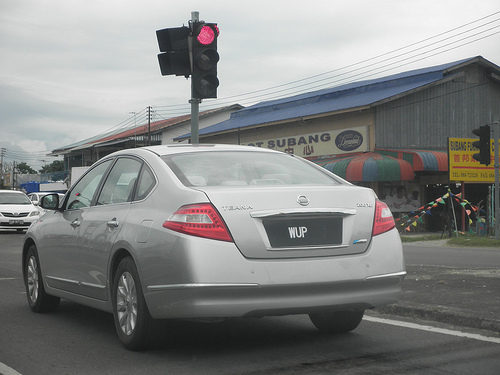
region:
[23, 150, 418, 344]
the car is silver in color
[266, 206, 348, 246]
the car has no numberplates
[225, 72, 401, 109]
the roof is blue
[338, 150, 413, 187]
the awing i red and blue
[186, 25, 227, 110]
the traaffic light is red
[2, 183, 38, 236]
the car is white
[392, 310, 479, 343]
the line is white in color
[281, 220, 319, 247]
wup letters are on the plate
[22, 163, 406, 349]
the car is brand new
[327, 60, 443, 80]
electric wires are in the air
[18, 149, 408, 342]
a silver car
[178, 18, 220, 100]
a street sign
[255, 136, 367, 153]
writing on the side of the building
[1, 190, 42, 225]
a white car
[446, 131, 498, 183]
a yellow sign on the building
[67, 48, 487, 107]
wires from the telephone poles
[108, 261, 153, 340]
the tire of the car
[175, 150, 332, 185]
the back window of the car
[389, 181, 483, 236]
flags in front of the building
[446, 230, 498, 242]
grass in front of the building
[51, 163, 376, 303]
this is a car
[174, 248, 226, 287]
the car is white in color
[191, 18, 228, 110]
this is a traffic light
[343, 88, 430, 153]
this is a building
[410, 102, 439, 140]
this is the wall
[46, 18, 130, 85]
this is the sky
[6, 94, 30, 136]
the sky is blue in color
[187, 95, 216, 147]
this is a pole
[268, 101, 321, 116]
this is the roof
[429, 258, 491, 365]
this is the road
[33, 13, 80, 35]
this is the sky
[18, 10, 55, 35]
the sky is blue in color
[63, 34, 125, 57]
the sky is bright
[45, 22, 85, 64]
the sky has clouds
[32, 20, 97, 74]
the clouds are white in color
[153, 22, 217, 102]
this is a traffic light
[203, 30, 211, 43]
the light is red in color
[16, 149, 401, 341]
this is a car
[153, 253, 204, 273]
the car is grey in color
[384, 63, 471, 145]
this is a building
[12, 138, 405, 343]
Car is stopped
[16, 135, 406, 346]
Silver car is stopped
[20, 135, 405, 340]
Car stopped at a light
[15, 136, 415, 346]
Car is stopped at a light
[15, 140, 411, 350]
Silver car stopped at a light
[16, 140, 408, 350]
Silver car is stopped at a light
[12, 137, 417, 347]
Car stopped at a red light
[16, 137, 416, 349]
Car is stopped at a red light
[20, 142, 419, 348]
Silver car stopped at a red light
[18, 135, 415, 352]
Silver car is stopped at a red light